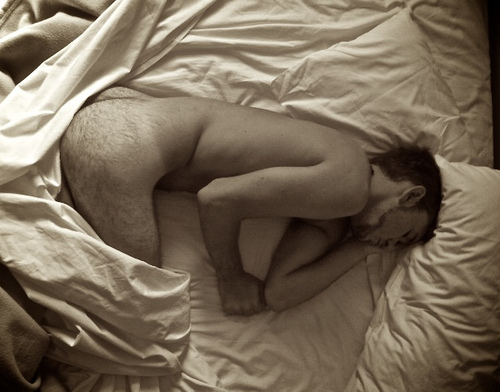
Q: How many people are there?
A: One.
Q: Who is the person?
A: A man.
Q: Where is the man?
A: In bed.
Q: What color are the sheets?
A: White.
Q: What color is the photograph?
A: Black and white.